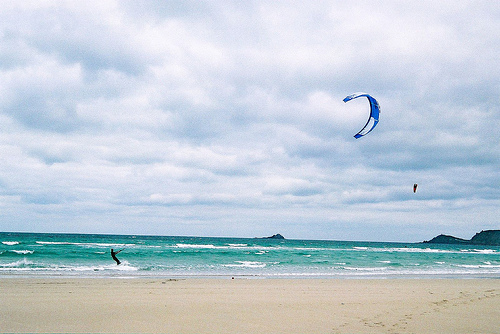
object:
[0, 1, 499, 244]
sky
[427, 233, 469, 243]
mountains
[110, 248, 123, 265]
person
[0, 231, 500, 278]
water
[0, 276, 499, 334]
sand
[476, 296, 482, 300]
tracks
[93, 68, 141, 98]
clouds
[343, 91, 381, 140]
kite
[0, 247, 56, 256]
wave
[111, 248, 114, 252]
head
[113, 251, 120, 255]
arms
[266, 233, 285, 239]
island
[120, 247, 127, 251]
handle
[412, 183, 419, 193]
kite